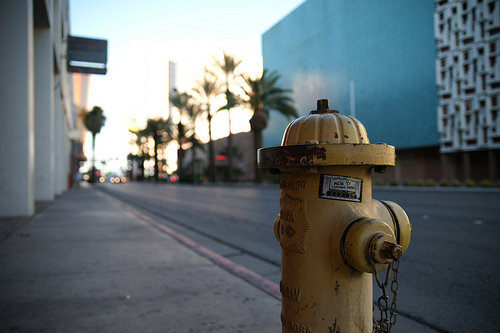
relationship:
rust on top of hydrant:
[251, 138, 325, 172] [255, 97, 412, 331]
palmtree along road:
[237, 66, 300, 186] [87, 174, 496, 329]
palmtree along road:
[210, 50, 247, 185] [87, 174, 496, 329]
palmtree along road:
[193, 66, 223, 180] [87, 174, 496, 329]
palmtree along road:
[185, 101, 206, 183] [87, 174, 496, 329]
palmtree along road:
[169, 84, 193, 183] [87, 174, 496, 329]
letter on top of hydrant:
[280, 279, 285, 294] [255, 97, 412, 331]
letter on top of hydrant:
[284, 285, 289, 295] [255, 97, 412, 331]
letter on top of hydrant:
[292, 284, 302, 303] [255, 97, 412, 331]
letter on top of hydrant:
[281, 208, 287, 217] [255, 97, 412, 331]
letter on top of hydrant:
[288, 208, 294, 222] [255, 97, 412, 331]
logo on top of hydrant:
[277, 191, 310, 255] [255, 97, 412, 331]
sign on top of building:
[66, 31, 111, 75] [0, 1, 80, 219]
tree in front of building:
[237, 66, 300, 186] [253, 0, 441, 157]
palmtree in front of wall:
[237, 66, 300, 186] [253, 0, 441, 157]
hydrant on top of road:
[255, 97, 412, 331] [87, 174, 496, 329]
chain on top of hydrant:
[367, 256, 401, 332] [255, 97, 412, 331]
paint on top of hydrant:
[257, 106, 397, 194] [255, 97, 412, 331]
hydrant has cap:
[255, 97, 412, 331] [255, 98, 397, 168]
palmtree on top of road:
[237, 66, 300, 186] [87, 174, 496, 329]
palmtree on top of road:
[210, 50, 247, 185] [87, 174, 496, 329]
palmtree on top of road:
[193, 66, 223, 180] [87, 174, 496, 329]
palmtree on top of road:
[185, 101, 206, 183] [87, 174, 496, 329]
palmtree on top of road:
[169, 84, 193, 183] [87, 174, 496, 329]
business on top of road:
[0, 1, 80, 219] [87, 174, 496, 329]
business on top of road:
[67, 27, 92, 191] [87, 174, 496, 329]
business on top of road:
[175, 126, 261, 180] [87, 174, 496, 329]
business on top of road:
[253, 0, 441, 157] [87, 174, 496, 329]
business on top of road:
[435, 0, 499, 185] [87, 174, 496, 329]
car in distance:
[113, 173, 126, 180] [81, 94, 157, 195]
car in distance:
[101, 177, 113, 182] [81, 94, 157, 195]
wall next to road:
[253, 0, 441, 157] [87, 174, 496, 329]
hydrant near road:
[255, 97, 412, 331] [87, 174, 496, 329]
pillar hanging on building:
[0, 0, 36, 220] [0, 1, 80, 219]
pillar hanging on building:
[37, 17, 52, 209] [0, 1, 80, 219]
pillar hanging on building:
[57, 99, 67, 194] [0, 1, 80, 219]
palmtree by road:
[237, 66, 300, 186] [87, 174, 496, 329]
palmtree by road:
[210, 50, 247, 185] [87, 174, 496, 329]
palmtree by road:
[193, 66, 223, 180] [87, 174, 496, 329]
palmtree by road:
[185, 101, 206, 183] [87, 174, 496, 329]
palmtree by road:
[169, 84, 193, 183] [87, 174, 496, 329]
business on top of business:
[435, 0, 499, 185] [435, 0, 499, 185]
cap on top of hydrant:
[255, 98, 397, 168] [255, 97, 412, 331]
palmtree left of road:
[84, 104, 107, 187] [87, 174, 496, 329]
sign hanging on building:
[66, 31, 111, 75] [0, 1, 80, 219]